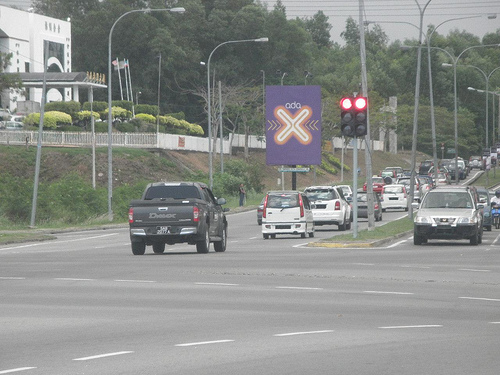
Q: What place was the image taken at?
A: It was taken at the road.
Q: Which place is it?
A: It is a road.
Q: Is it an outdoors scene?
A: Yes, it is outdoors.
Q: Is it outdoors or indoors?
A: It is outdoors.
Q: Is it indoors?
A: No, it is outdoors.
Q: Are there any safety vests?
A: No, there are no safety vests.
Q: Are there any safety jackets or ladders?
A: No, there are no safety jackets or ladders.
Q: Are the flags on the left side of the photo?
A: Yes, the flags are on the left of the image.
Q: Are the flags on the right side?
A: No, the flags are on the left of the image.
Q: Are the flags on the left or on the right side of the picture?
A: The flags are on the left of the image.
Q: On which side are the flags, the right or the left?
A: The flags are on the left of the image.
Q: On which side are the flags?
A: The flags are on the left of the image.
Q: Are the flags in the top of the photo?
A: Yes, the flags are in the top of the image.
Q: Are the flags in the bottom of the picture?
A: No, the flags are in the top of the image.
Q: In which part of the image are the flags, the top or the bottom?
A: The flags are in the top of the image.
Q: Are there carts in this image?
A: No, there are no carts.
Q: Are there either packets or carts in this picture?
A: No, there are no carts or packets.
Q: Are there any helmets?
A: No, there are no helmets.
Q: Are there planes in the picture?
A: No, there are no planes.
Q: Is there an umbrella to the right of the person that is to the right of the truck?
A: No, there is a vehicle to the right of the person.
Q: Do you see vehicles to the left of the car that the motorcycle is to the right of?
A: Yes, there is a vehicle to the left of the car.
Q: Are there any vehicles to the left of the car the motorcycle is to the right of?
A: Yes, there is a vehicle to the left of the car.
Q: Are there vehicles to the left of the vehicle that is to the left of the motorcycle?
A: Yes, there is a vehicle to the left of the car.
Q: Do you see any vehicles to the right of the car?
A: No, the vehicle is to the left of the car.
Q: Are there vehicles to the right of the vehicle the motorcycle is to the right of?
A: No, the vehicle is to the left of the car.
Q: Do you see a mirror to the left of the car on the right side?
A: No, there is a vehicle to the left of the car.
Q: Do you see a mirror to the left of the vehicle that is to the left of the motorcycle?
A: No, there is a vehicle to the left of the car.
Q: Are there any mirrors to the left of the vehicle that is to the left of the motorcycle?
A: No, there is a vehicle to the left of the car.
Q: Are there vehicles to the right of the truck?
A: Yes, there is a vehicle to the right of the truck.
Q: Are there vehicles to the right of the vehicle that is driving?
A: Yes, there is a vehicle to the right of the truck.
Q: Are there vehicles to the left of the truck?
A: No, the vehicle is to the right of the truck.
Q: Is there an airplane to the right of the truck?
A: No, there is a vehicle to the right of the truck.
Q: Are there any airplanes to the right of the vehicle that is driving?
A: No, there is a vehicle to the right of the truck.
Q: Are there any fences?
A: Yes, there is a fence.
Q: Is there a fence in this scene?
A: Yes, there is a fence.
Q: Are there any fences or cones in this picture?
A: Yes, there is a fence.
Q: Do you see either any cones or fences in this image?
A: Yes, there is a fence.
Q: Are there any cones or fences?
A: Yes, there is a fence.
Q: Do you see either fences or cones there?
A: Yes, there is a fence.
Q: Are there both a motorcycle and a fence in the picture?
A: Yes, there are both a fence and a motorcycle.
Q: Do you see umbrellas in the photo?
A: No, there are no umbrellas.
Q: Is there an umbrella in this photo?
A: No, there are no umbrellas.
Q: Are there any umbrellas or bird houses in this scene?
A: No, there are no umbrellas or bird houses.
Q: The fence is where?
A: The fence is on the hill.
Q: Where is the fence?
A: The fence is on the hill.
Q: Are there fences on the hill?
A: Yes, there is a fence on the hill.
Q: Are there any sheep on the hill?
A: No, there is a fence on the hill.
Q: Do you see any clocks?
A: No, there are no clocks.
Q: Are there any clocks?
A: No, there are no clocks.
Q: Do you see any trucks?
A: Yes, there is a truck.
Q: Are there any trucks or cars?
A: Yes, there is a truck.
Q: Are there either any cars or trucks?
A: Yes, there is a truck.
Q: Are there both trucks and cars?
A: Yes, there are both a truck and a car.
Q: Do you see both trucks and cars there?
A: Yes, there are both a truck and a car.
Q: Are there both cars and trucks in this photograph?
A: Yes, there are both a truck and a car.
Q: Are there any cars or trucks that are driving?
A: Yes, the truck is driving.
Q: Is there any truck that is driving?
A: Yes, there is a truck that is driving.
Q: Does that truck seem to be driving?
A: Yes, the truck is driving.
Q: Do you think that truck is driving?
A: Yes, the truck is driving.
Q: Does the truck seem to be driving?
A: Yes, the truck is driving.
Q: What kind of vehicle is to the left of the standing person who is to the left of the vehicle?
A: The vehicle is a truck.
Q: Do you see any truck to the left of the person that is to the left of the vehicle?
A: Yes, there is a truck to the left of the person.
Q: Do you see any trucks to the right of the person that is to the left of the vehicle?
A: No, the truck is to the left of the person.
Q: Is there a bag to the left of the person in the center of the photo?
A: No, there is a truck to the left of the person.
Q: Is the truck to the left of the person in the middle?
A: Yes, the truck is to the left of the person.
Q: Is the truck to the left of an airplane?
A: No, the truck is to the left of the person.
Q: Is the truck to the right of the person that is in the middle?
A: No, the truck is to the left of the person.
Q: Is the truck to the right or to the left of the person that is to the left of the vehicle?
A: The truck is to the left of the person.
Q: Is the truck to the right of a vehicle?
A: No, the truck is to the left of a vehicle.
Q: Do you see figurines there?
A: No, there are no figurines.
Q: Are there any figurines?
A: No, there are no figurines.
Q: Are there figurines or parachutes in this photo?
A: No, there are no figurines or parachutes.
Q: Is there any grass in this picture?
A: Yes, there is grass.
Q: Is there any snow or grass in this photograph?
A: Yes, there is grass.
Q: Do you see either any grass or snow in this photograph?
A: Yes, there is grass.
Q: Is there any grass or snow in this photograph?
A: Yes, there is grass.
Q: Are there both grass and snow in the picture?
A: No, there is grass but no snow.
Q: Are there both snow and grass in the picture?
A: No, there is grass but no snow.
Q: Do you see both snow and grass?
A: No, there is grass but no snow.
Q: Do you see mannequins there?
A: No, there are no mannequins.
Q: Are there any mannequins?
A: No, there are no mannequins.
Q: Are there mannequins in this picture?
A: No, there are no mannequins.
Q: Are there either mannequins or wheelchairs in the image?
A: No, there are no mannequins or wheelchairs.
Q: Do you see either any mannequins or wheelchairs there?
A: No, there are no mannequins or wheelchairs.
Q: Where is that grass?
A: The grass is on the hill.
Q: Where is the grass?
A: The grass is on the hill.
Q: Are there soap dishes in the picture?
A: No, there are no soap dishes.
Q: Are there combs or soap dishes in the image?
A: No, there are no soap dishes or combs.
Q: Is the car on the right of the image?
A: Yes, the car is on the right of the image.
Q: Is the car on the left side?
A: No, the car is on the right of the image.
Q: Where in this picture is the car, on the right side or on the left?
A: The car is on the right of the image.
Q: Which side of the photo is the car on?
A: The car is on the right of the image.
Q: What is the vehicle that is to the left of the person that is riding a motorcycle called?
A: The vehicle is a car.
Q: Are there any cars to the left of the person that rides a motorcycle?
A: Yes, there is a car to the left of the person.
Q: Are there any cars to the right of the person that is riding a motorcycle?
A: No, the car is to the left of the person.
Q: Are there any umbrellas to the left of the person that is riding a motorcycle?
A: No, there is a car to the left of the person.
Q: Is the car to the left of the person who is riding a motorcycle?
A: Yes, the car is to the left of the person.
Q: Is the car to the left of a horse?
A: No, the car is to the left of the person.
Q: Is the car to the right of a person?
A: No, the car is to the left of a person.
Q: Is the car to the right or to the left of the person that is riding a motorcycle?
A: The car is to the left of the person.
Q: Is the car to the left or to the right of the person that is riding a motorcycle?
A: The car is to the left of the person.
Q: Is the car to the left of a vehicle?
A: No, the car is to the right of a vehicle.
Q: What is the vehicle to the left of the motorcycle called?
A: The vehicle is a car.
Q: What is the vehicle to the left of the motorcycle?
A: The vehicle is a car.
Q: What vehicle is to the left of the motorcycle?
A: The vehicle is a car.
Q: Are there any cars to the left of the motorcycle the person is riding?
A: Yes, there is a car to the left of the motorbike.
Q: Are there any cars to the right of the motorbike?
A: No, the car is to the left of the motorbike.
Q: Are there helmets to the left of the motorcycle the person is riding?
A: No, there is a car to the left of the motorcycle.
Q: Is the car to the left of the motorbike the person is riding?
A: Yes, the car is to the left of the motorbike.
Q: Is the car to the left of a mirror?
A: No, the car is to the left of the motorbike.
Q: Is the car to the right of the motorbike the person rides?
A: No, the car is to the left of the motorbike.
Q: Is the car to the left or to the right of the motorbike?
A: The car is to the left of the motorbike.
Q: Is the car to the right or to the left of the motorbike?
A: The car is to the left of the motorbike.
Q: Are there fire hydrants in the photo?
A: No, there are no fire hydrants.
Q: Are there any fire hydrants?
A: No, there are no fire hydrants.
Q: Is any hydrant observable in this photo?
A: No, there are no fire hydrants.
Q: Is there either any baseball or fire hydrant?
A: No, there are no fire hydrants or baseballs.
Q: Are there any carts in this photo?
A: No, there are no carts.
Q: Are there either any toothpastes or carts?
A: No, there are no carts or toothpastes.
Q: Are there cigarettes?
A: No, there are no cigarettes.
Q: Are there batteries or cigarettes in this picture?
A: No, there are no cigarettes or batteries.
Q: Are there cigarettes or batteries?
A: No, there are no cigarettes or batteries.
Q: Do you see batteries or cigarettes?
A: No, there are no cigarettes or batteries.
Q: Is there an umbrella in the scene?
A: No, there are no umbrellas.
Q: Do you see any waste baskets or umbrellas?
A: No, there are no umbrellas or waste baskets.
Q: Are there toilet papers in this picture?
A: No, there are no toilet papers.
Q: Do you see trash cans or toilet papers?
A: No, there are no toilet papers or trash cans.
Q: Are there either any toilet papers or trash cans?
A: No, there are no toilet papers or trash cans.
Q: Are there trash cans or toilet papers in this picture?
A: No, there are no toilet papers or trash cans.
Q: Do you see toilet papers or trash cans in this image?
A: No, there are no toilet papers or trash cans.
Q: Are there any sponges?
A: No, there are no sponges.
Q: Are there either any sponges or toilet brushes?
A: No, there are no sponges or toilet brushes.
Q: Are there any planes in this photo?
A: No, there are no planes.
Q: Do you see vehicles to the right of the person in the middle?
A: Yes, there is a vehicle to the right of the person.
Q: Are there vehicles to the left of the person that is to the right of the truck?
A: No, the vehicle is to the right of the person.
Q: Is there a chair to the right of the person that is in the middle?
A: No, there is a vehicle to the right of the person.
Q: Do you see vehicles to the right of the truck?
A: Yes, there is a vehicle to the right of the truck.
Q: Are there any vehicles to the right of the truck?
A: Yes, there is a vehicle to the right of the truck.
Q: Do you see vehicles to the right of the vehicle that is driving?
A: Yes, there is a vehicle to the right of the truck.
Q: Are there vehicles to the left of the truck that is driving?
A: No, the vehicle is to the right of the truck.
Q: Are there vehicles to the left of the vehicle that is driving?
A: No, the vehicle is to the right of the truck.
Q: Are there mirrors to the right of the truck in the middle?
A: No, there is a vehicle to the right of the truck.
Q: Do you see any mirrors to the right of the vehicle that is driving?
A: No, there is a vehicle to the right of the truck.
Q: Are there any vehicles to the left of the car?
A: Yes, there is a vehicle to the left of the car.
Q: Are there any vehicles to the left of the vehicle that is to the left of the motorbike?
A: Yes, there is a vehicle to the left of the car.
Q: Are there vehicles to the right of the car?
A: No, the vehicle is to the left of the car.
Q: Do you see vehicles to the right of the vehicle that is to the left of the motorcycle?
A: No, the vehicle is to the left of the car.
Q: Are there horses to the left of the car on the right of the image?
A: No, there is a vehicle to the left of the car.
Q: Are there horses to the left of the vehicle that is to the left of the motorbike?
A: No, there is a vehicle to the left of the car.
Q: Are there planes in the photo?
A: No, there are no planes.